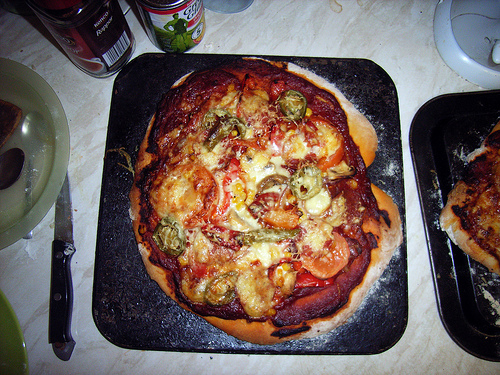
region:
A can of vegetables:
[136, 0, 218, 49]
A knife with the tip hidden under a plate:
[46, 170, 76, 357]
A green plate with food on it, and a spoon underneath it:
[0, 64, 72, 257]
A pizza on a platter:
[90, 53, 405, 360]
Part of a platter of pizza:
[409, 88, 499, 363]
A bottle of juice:
[22, 1, 136, 76]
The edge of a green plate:
[1, 288, 38, 373]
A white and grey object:
[431, 0, 498, 82]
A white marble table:
[94, 350, 446, 373]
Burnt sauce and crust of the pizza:
[266, 290, 360, 337]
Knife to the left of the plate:
[53, 213, 81, 366]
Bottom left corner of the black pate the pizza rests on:
[96, 256, 158, 356]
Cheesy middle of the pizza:
[216, 155, 328, 234]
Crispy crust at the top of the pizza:
[159, 61, 247, 89]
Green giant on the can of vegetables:
[161, 10, 196, 51]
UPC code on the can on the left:
[101, 32, 134, 64]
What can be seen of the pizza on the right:
[451, 121, 488, 274]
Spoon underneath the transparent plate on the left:
[19, 110, 44, 245]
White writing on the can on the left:
[89, 16, 119, 38]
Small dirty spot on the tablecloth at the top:
[323, 0, 349, 19]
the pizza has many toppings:
[131, 60, 397, 344]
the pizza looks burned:
[128, 58, 398, 340]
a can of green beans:
[133, 0, 203, 50]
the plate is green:
[0, 56, 70, 247]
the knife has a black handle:
[48, 171, 75, 361]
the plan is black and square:
[93, 52, 405, 354]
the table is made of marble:
[0, 0, 499, 372]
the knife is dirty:
[50, 164, 75, 360]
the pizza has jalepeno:
[135, 58, 398, 343]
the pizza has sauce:
[129, 57, 396, 337]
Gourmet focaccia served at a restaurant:
[133, 60, 380, 332]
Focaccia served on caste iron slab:
[120, 54, 411, 363]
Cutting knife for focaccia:
[33, 131, 106, 371]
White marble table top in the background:
[63, 45, 431, 373]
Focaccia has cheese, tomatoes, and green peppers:
[130, 56, 380, 332]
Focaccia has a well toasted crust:
[140, 66, 396, 348]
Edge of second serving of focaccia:
[410, 70, 496, 355]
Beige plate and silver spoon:
[0, 68, 62, 256]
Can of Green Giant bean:
[142, 0, 211, 66]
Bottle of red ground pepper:
[40, 6, 131, 84]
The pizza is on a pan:
[88, 86, 457, 346]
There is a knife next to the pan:
[22, 162, 122, 346]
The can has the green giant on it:
[141, 10, 243, 77]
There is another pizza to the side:
[399, 79, 497, 291]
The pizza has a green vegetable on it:
[131, 142, 285, 347]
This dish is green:
[1, 296, 23, 364]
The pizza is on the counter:
[234, 14, 464, 196]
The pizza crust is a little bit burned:
[254, 306, 324, 361]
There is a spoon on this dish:
[0, 91, 50, 276]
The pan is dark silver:
[86, 179, 221, 374]